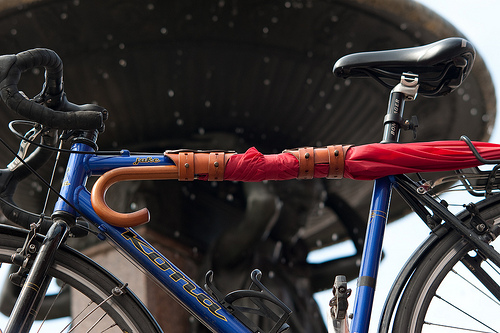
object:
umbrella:
[85, 139, 498, 228]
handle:
[88, 161, 178, 229]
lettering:
[119, 230, 152, 256]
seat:
[326, 35, 478, 98]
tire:
[0, 229, 159, 333]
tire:
[390, 200, 498, 333]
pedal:
[328, 275, 352, 321]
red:
[217, 140, 497, 182]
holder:
[203, 269, 293, 332]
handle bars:
[0, 47, 103, 142]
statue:
[207, 156, 325, 332]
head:
[261, 180, 329, 247]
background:
[0, 180, 500, 333]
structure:
[0, 0, 497, 333]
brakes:
[462, 201, 500, 243]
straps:
[177, 149, 197, 185]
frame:
[51, 135, 403, 332]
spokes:
[68, 286, 125, 333]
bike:
[0, 36, 500, 333]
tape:
[19, 102, 65, 126]